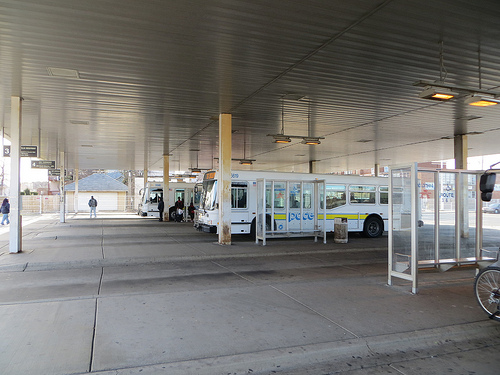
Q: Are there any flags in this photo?
A: No, there are no flags.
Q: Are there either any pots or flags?
A: No, there are no flags or pots.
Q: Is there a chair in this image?
A: No, there are no chairs.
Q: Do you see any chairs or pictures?
A: No, there are no chairs or pictures.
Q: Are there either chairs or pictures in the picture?
A: No, there are no chairs or pictures.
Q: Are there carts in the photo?
A: No, there are no carts.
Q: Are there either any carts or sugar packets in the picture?
A: No, there are no carts or sugar packets.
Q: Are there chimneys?
A: No, there are no chimneys.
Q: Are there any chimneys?
A: No, there are no chimneys.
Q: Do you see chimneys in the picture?
A: No, there are no chimneys.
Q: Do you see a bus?
A: Yes, there is a bus.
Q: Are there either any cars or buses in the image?
A: Yes, there is a bus.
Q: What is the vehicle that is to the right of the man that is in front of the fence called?
A: The vehicle is a bus.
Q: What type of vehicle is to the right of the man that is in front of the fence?
A: The vehicle is a bus.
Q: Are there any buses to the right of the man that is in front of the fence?
A: Yes, there is a bus to the right of the man.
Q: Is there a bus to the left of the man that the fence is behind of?
A: No, the bus is to the right of the man.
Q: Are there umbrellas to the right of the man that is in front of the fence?
A: No, there is a bus to the right of the man.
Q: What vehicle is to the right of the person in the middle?
A: The vehicle is a bus.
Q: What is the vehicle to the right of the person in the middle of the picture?
A: The vehicle is a bus.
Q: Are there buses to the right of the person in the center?
A: Yes, there is a bus to the right of the person.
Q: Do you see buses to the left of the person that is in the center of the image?
A: No, the bus is to the right of the person.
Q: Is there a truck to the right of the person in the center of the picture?
A: No, there is a bus to the right of the person.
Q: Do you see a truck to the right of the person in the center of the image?
A: No, there is a bus to the right of the person.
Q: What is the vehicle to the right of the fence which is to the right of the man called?
A: The vehicle is a bus.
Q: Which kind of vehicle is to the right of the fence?
A: The vehicle is a bus.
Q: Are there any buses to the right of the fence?
A: Yes, there is a bus to the right of the fence.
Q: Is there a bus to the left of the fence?
A: No, the bus is to the right of the fence.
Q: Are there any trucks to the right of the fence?
A: No, there is a bus to the right of the fence.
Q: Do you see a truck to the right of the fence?
A: No, there is a bus to the right of the fence.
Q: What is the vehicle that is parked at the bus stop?
A: The vehicle is a bus.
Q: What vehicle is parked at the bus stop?
A: The vehicle is a bus.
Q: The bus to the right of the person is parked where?
A: The bus is parked at the bus stop.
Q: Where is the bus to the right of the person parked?
A: The bus is parked at the bus stop.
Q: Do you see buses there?
A: Yes, there is a bus.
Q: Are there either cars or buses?
A: Yes, there is a bus.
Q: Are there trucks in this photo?
A: No, there are no trucks.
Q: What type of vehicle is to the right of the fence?
A: The vehicle is a bus.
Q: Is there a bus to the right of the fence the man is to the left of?
A: Yes, there is a bus to the right of the fence.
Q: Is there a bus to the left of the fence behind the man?
A: No, the bus is to the right of the fence.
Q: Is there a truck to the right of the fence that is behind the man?
A: No, there is a bus to the right of the fence.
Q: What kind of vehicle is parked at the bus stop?
A: The vehicle is a bus.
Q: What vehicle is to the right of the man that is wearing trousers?
A: The vehicle is a bus.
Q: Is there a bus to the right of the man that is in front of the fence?
A: Yes, there is a bus to the right of the man.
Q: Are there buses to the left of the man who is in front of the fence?
A: No, the bus is to the right of the man.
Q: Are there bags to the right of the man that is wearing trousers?
A: No, there is a bus to the right of the man.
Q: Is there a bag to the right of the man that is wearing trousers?
A: No, there is a bus to the right of the man.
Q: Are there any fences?
A: Yes, there is a fence.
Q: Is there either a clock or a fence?
A: Yes, there is a fence.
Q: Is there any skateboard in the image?
A: No, there are no skateboards.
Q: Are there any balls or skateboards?
A: No, there are no skateboards or balls.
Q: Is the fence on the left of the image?
A: Yes, the fence is on the left of the image.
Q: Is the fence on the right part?
A: No, the fence is on the left of the image.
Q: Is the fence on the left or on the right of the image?
A: The fence is on the left of the image.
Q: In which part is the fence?
A: The fence is on the left of the image.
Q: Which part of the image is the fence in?
A: The fence is on the left of the image.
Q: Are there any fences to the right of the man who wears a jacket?
A: Yes, there is a fence to the right of the man.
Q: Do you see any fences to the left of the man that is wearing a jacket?
A: No, the fence is to the right of the man.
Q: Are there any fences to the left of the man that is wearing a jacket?
A: No, the fence is to the right of the man.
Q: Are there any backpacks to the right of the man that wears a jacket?
A: No, there is a fence to the right of the man.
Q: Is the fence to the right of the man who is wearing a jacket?
A: Yes, the fence is to the right of the man.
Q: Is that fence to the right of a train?
A: No, the fence is to the right of the man.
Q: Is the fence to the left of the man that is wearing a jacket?
A: No, the fence is to the right of the man.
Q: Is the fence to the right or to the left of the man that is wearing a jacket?
A: The fence is to the right of the man.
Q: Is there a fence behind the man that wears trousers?
A: Yes, there is a fence behind the man.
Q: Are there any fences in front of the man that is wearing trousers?
A: No, the fence is behind the man.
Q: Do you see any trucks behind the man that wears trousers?
A: No, there is a fence behind the man.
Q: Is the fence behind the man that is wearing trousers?
A: Yes, the fence is behind the man.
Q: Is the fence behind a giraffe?
A: No, the fence is behind the man.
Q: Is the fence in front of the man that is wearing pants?
A: No, the fence is behind the man.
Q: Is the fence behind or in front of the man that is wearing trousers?
A: The fence is behind the man.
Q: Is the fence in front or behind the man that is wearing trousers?
A: The fence is behind the man.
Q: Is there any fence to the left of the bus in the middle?
A: Yes, there is a fence to the left of the bus.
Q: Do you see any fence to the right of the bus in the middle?
A: No, the fence is to the left of the bus.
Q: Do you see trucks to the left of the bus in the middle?
A: No, there is a fence to the left of the bus.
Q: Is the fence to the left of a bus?
A: Yes, the fence is to the left of a bus.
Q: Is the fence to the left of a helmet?
A: No, the fence is to the left of a bus.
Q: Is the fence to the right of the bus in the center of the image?
A: No, the fence is to the left of the bus.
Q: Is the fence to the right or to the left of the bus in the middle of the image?
A: The fence is to the left of the bus.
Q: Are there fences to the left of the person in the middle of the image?
A: Yes, there is a fence to the left of the person.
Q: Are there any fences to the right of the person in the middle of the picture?
A: No, the fence is to the left of the person.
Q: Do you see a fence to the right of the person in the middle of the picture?
A: No, the fence is to the left of the person.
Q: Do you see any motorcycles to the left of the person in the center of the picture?
A: No, there is a fence to the left of the person.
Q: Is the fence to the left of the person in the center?
A: Yes, the fence is to the left of the person.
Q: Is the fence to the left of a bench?
A: No, the fence is to the left of the person.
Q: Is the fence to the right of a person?
A: No, the fence is to the left of a person.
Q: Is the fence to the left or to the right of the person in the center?
A: The fence is to the left of the person.